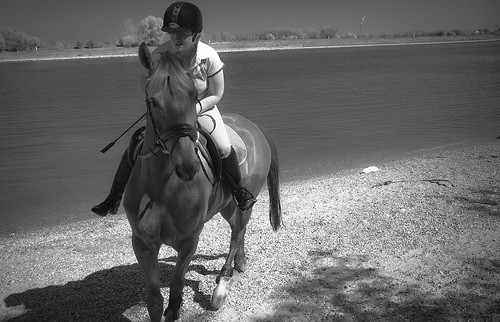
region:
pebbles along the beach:
[316, 162, 498, 258]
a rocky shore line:
[303, 126, 499, 208]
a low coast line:
[219, 21, 485, 53]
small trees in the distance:
[3, 22, 45, 61]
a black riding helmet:
[149, 0, 209, 40]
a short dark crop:
[78, 91, 150, 155]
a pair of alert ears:
[134, 37, 213, 71]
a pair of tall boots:
[83, 143, 261, 222]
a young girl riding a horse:
[98, 1, 254, 229]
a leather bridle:
[137, 43, 221, 185]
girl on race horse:
[85, 0, 285, 320]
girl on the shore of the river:
[3, 138, 499, 320]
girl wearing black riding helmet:
[157, 2, 208, 40]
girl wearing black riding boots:
[88, 137, 256, 220]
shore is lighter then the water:
[5, 157, 496, 317]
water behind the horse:
[1, 42, 498, 235]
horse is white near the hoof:
[208, 265, 234, 315]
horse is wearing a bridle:
[143, 90, 210, 172]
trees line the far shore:
[0, 14, 499, 57]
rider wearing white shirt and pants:
[146, 43, 235, 157]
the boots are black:
[105, 156, 122, 227]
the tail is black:
[264, 178, 296, 224]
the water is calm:
[298, 64, 463, 147]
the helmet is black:
[159, 0, 216, 40]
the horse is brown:
[145, 108, 277, 319]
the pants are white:
[185, 61, 250, 145]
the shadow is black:
[19, 251, 184, 318]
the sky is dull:
[21, 13, 472, 24]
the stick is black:
[93, 113, 145, 155]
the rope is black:
[156, 132, 210, 148]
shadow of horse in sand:
[32, 265, 163, 316]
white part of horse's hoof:
[206, 275, 251, 305]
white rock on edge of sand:
[355, 157, 387, 178]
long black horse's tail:
[255, 130, 292, 234]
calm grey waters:
[304, 98, 429, 141]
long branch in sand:
[372, 175, 474, 193]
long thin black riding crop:
[97, 105, 152, 166]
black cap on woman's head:
[149, 5, 216, 46]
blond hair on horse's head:
[145, 57, 197, 105]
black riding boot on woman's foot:
[89, 149, 162, 245]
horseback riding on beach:
[95, 7, 423, 318]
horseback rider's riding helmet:
[155, 7, 220, 49]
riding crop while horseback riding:
[77, 99, 158, 153]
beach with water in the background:
[306, 21, 478, 316]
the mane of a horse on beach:
[254, 108, 301, 247]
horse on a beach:
[116, 57, 281, 296]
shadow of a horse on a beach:
[15, 262, 262, 319]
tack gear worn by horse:
[127, 92, 215, 184]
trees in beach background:
[1, 22, 375, 88]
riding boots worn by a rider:
[88, 110, 268, 235]